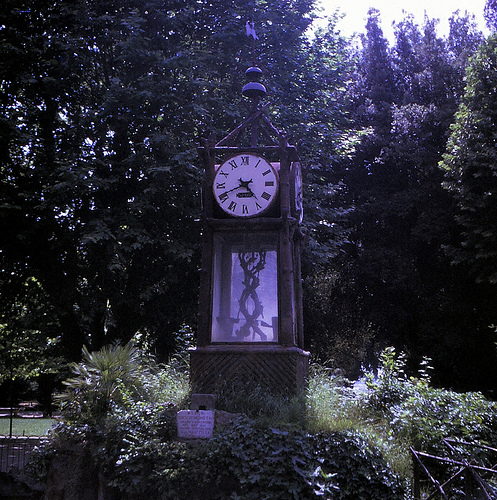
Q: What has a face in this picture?
A: Clock.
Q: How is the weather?
A: Sunny.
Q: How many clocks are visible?
A: One.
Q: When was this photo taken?
A: During the daytime.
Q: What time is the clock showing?
A: 4:42.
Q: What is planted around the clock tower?
A: Vegetation.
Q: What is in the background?
A: Trees.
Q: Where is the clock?
A: Near the top of the tower.